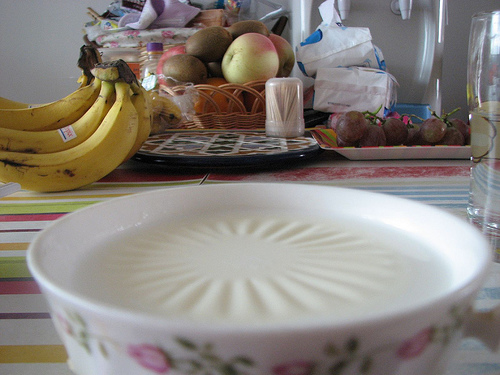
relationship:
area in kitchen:
[7, 7, 494, 357] [6, 5, 490, 173]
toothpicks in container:
[267, 83, 301, 124] [263, 75, 307, 139]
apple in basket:
[217, 29, 285, 93] [116, 79, 305, 131]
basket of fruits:
[116, 79, 305, 131] [142, 20, 293, 84]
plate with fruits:
[310, 121, 486, 164] [331, 108, 472, 145]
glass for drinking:
[456, 7, 498, 242] [467, 9, 499, 32]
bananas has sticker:
[1, 59, 150, 194] [53, 125, 81, 146]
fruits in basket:
[142, 20, 293, 84] [153, 79, 269, 130]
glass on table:
[456, 7, 498, 242] [7, 151, 487, 375]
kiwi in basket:
[160, 49, 211, 90] [116, 79, 305, 131]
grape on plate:
[332, 109, 375, 142] [310, 121, 486, 164]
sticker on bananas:
[53, 125, 81, 146] [1, 59, 150, 194]